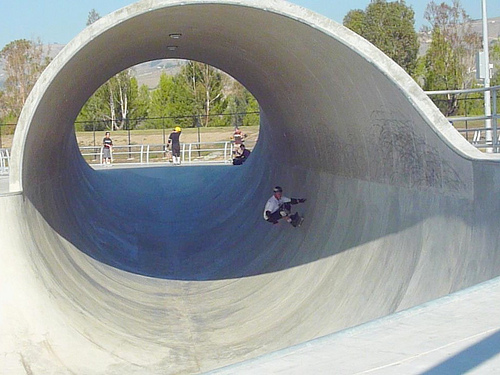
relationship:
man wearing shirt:
[263, 186, 308, 228] [263, 194, 293, 214]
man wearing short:
[84, 130, 118, 167] [100, 146, 110, 159]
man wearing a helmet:
[164, 122, 184, 164] [171, 124, 183, 136]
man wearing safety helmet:
[263, 186, 308, 228] [271, 184, 286, 200]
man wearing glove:
[263, 186, 308, 228] [292, 190, 309, 207]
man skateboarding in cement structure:
[263, 185, 307, 225] [0, 0, 498, 374]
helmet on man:
[271, 184, 286, 195] [262, 184, 305, 235]